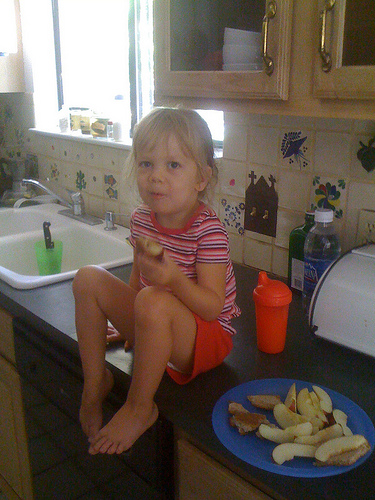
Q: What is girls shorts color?
A: Red.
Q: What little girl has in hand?
A: Fruit.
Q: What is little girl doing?
A: Eating.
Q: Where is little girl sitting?
A: Kitchen counter.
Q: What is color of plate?
A: Blue.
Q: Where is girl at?
A: Kitchen.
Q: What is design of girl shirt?
A: Stripes.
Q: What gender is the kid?
A: Female.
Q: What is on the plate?
A: Apples.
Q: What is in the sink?
A: A cup and knife.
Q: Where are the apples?
A: On a plate.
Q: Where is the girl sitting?
A: On the counter.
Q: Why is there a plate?
A: To serve the food.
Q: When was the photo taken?
A: Daytime.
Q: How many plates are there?
A: One.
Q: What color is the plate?
A: Blue.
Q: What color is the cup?
A: Red.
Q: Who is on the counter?
A: The girl.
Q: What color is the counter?
A: Black.